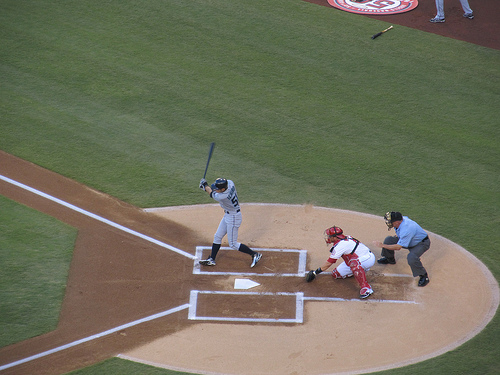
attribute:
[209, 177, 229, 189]
helmet — black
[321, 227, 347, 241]
helmet — red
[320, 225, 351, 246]
catcher's head — red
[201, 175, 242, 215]
shirt — green, gray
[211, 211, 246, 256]
pants — grey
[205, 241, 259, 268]
socks — black, long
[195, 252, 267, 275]
shoes — white, black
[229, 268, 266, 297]
plate — white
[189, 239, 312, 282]
lines — white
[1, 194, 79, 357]
grass — green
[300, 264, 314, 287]
glove — dark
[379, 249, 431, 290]
feet — black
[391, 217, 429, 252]
shirt — blue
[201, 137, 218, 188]
bat — black